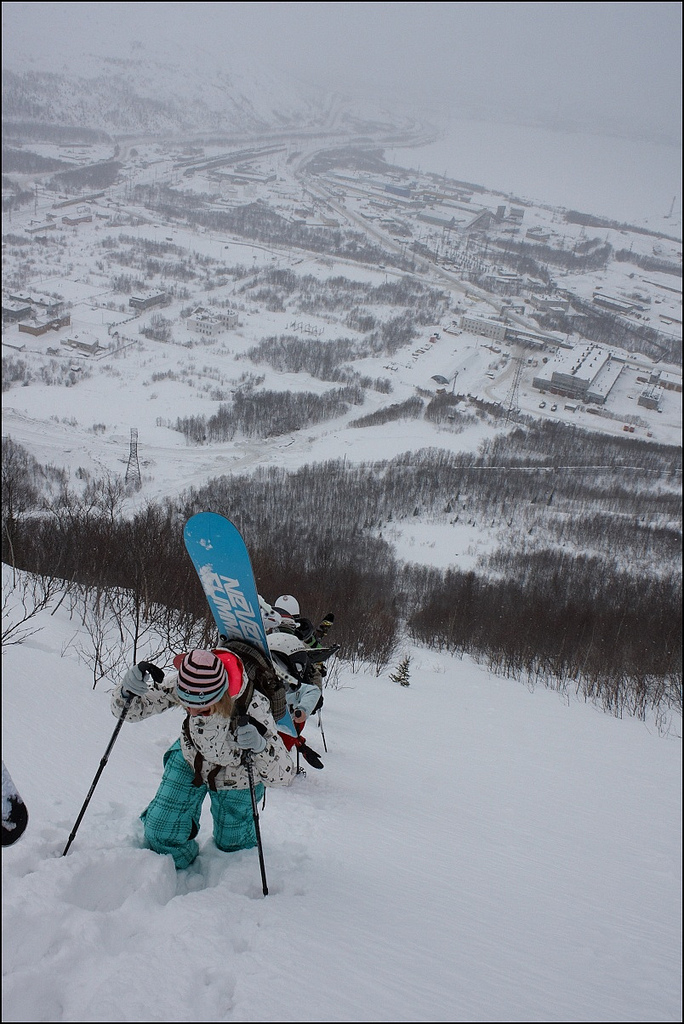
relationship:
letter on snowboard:
[213, 578, 242, 602] [179, 513, 268, 654]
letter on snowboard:
[218, 578, 245, 595] [184, 506, 268, 647]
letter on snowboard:
[216, 570, 245, 597] [184, 511, 261, 640]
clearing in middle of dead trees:
[383, 509, 493, 582] [439, 570, 598, 643]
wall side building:
[558, 379, 570, 393] [526, 335, 632, 409]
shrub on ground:
[573, 576, 630, 717] [528, 675, 682, 762]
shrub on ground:
[556, 566, 635, 720] [431, 673, 682, 849]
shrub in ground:
[540, 604, 567, 667] [307, 659, 682, 968]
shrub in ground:
[473, 606, 536, 678] [425, 685, 682, 990]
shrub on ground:
[343, 615, 400, 658] [340, 647, 682, 1017]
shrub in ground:
[381, 647, 425, 685] [318, 670, 682, 1021]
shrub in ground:
[69, 550, 112, 632] [318, 670, 682, 1021]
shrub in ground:
[120, 562, 161, 666] [333, 694, 671, 1021]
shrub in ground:
[84, 531, 139, 611] [318, 670, 682, 1021]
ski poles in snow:
[60, 685, 278, 883] [24, 838, 407, 1022]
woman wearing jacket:
[139, 644, 283, 882] [118, 671, 295, 789]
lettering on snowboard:
[195, 565, 269, 643] [170, 507, 284, 652]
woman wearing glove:
[107, 638, 299, 876] [110, 651, 157, 711]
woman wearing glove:
[107, 638, 299, 876] [226, 722, 273, 759]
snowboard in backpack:
[177, 507, 303, 743] [222, 629, 290, 712]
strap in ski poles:
[136, 656, 172, 695] [60, 722, 291, 902]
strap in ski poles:
[226, 707, 275, 736] [60, 722, 291, 902]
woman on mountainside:
[107, 638, 299, 876] [31, 169, 660, 622]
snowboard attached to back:
[177, 508, 271, 648] [217, 634, 284, 748]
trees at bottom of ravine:
[268, 526, 394, 591] [98, 456, 682, 684]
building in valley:
[530, 343, 633, 410] [333, 403, 682, 660]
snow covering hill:
[284, 871, 652, 1020] [177, 666, 678, 856]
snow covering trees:
[284, 871, 652, 1020] [287, 514, 631, 673]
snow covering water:
[451, 146, 488, 179] [391, 105, 682, 228]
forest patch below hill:
[196, 378, 339, 451] [50, 611, 681, 987]